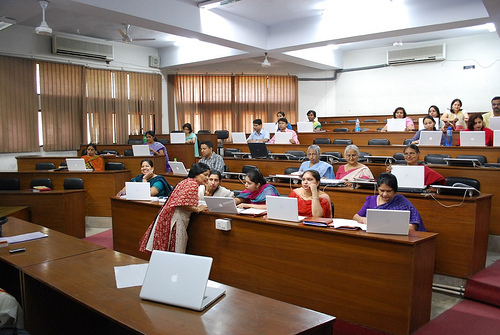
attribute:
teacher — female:
[140, 161, 210, 251]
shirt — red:
[295, 190, 333, 218]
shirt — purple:
[354, 195, 426, 227]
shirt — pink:
[340, 165, 373, 182]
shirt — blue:
[132, 174, 168, 196]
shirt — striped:
[197, 151, 229, 171]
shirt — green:
[180, 134, 200, 157]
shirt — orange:
[81, 155, 105, 172]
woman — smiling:
[123, 159, 167, 198]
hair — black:
[200, 141, 213, 150]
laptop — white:
[138, 241, 227, 310]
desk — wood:
[109, 197, 440, 330]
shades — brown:
[3, 54, 304, 148]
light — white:
[31, 1, 54, 40]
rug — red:
[412, 261, 496, 327]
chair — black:
[62, 176, 84, 189]